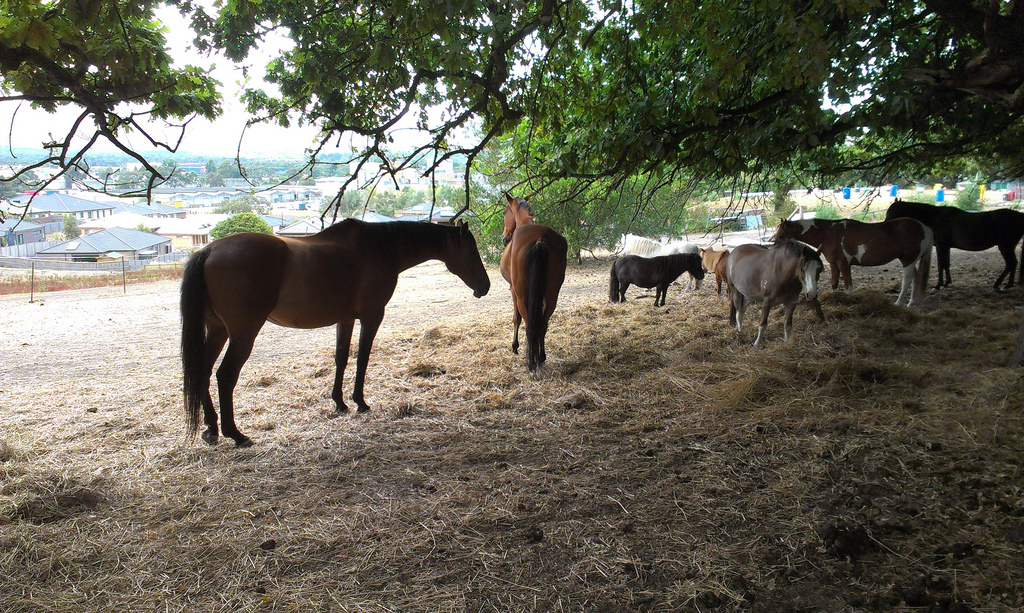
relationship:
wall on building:
[25, 232, 46, 239] [2, 225, 115, 271]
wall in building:
[41, 234, 68, 250] [8, 212, 164, 273]